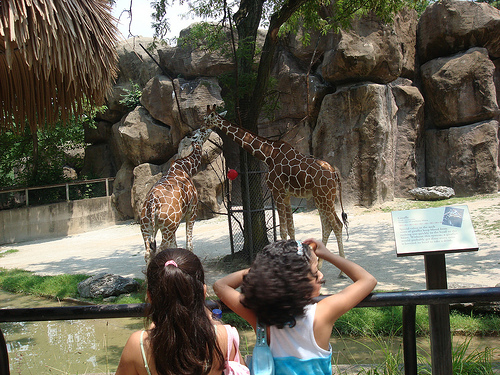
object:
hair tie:
[165, 260, 178, 268]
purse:
[253, 316, 274, 375]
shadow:
[25, 243, 146, 276]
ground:
[1, 193, 500, 334]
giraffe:
[141, 104, 350, 279]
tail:
[334, 172, 352, 237]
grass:
[382, 197, 475, 213]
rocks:
[82, 0, 500, 222]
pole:
[242, 149, 255, 266]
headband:
[296, 240, 304, 255]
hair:
[239, 239, 327, 330]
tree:
[216, 0, 431, 262]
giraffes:
[140, 102, 354, 281]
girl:
[118, 238, 378, 374]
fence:
[1, 287, 500, 375]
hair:
[141, 248, 225, 374]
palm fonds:
[1, 0, 144, 136]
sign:
[390, 204, 480, 255]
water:
[1, 290, 499, 374]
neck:
[222, 122, 267, 157]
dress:
[269, 303, 332, 375]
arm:
[213, 268, 248, 322]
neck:
[174, 145, 203, 174]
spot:
[227, 124, 239, 135]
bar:
[248, 171, 267, 174]